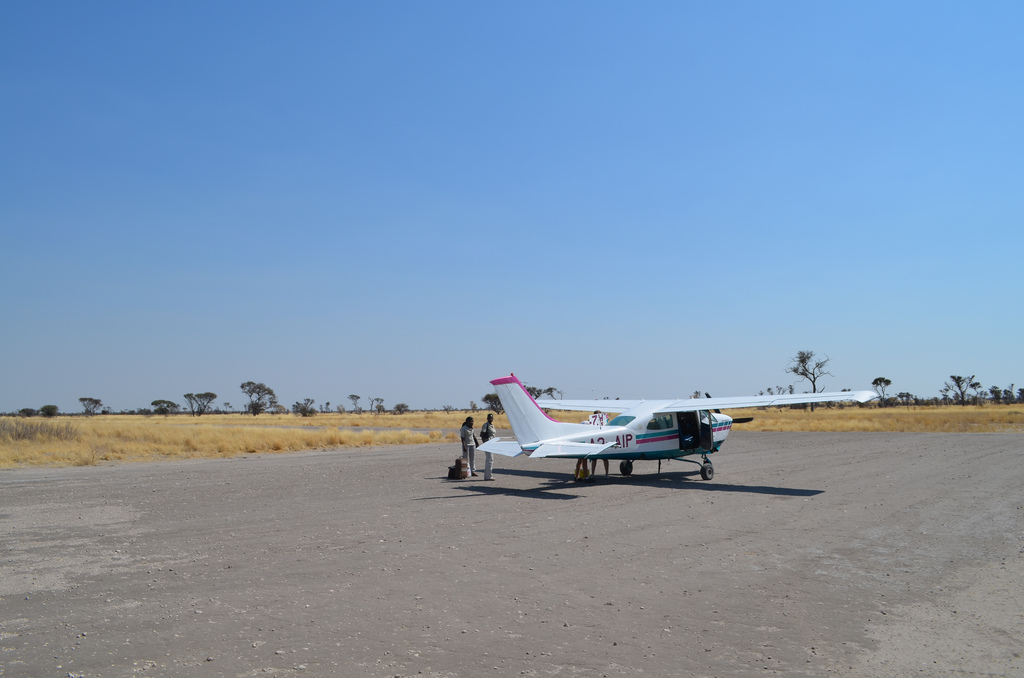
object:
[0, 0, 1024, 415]
sky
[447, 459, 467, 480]
bags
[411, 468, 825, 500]
shadow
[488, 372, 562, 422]
color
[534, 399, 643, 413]
wing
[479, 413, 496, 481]
people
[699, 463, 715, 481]
wheel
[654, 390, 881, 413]
wing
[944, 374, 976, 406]
tree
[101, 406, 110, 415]
tree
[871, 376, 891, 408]
tree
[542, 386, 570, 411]
tree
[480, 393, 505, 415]
tree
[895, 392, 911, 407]
tree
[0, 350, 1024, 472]
distance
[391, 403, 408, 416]
tree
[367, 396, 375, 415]
tree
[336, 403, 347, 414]
tree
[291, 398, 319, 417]
tree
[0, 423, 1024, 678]
grey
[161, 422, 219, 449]
brown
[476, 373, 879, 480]
airplane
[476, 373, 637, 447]
fin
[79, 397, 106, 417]
tree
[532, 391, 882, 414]
wings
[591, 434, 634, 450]
letters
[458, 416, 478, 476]
person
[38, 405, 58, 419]
tree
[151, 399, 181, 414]
tree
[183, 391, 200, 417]
tree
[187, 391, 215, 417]
tree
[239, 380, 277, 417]
tree